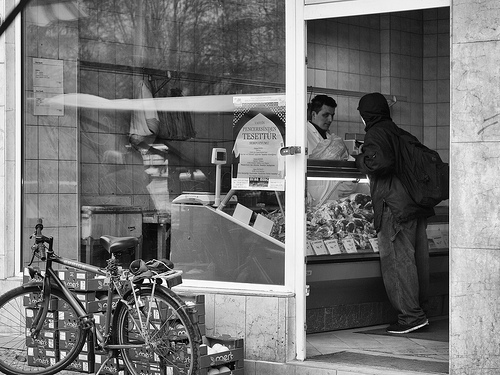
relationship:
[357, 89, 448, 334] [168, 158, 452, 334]
man standing at counter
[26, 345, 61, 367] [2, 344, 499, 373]
crate on top of ground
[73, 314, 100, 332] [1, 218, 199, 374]
pedal of bike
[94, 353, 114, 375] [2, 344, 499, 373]
kickstand on top of ground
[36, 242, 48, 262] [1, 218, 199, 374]
handle bar of bike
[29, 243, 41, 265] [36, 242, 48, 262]
brake of handle bar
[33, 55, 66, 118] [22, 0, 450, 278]
paper hanging on wall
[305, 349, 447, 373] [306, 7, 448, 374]
rug lying in doorway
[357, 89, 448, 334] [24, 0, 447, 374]
man standing in store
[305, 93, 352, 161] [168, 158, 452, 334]
man standing behind counter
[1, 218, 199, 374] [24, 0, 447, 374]
bike in front of store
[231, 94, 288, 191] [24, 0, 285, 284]
sign hanging in window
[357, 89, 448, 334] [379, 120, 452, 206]
man carrying backpack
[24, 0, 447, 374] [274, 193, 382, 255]
store sells food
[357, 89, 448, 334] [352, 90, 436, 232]
man wearing a hoodie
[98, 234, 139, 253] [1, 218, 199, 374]
seat of bike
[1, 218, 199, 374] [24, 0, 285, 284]
bike standing by window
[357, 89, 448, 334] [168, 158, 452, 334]
man leaning over counter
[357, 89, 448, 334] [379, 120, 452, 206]
man wearing a backpack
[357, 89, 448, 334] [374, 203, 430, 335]
man wearing jeans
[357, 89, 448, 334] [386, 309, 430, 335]
man wearing shoe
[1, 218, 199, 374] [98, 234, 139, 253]
bike has a seat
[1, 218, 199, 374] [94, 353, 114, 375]
bike has a kickstand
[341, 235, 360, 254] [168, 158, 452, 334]
sign on bottom of counter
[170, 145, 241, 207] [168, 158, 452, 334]
scale next to counter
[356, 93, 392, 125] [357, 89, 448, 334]
head of a man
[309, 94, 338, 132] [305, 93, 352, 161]
head of a man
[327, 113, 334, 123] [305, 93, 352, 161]
nose of a man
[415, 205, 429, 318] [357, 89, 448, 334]
leg of a man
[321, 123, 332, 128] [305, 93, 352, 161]
mouth of a man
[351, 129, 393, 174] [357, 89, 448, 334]
arm of a man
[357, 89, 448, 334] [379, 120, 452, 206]
man wearing backpack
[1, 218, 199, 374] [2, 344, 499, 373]
bike on top of ground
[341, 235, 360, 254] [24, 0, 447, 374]
sign hanging in store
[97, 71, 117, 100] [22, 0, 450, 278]
tile hanging on wall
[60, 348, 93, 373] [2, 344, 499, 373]
crate on top of ground